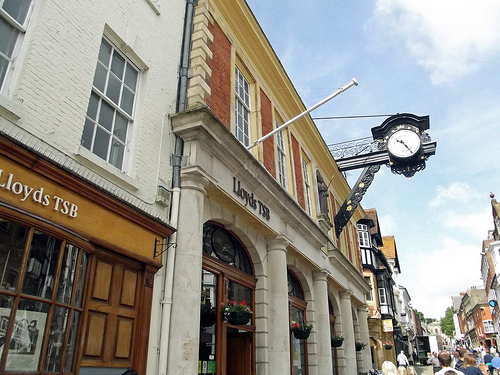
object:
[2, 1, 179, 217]
wall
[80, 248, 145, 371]
door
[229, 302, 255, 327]
basket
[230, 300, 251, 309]
flowers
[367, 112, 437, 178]
clock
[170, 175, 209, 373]
pillar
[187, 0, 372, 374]
building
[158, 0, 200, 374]
downspout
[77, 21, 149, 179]
window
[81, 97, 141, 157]
panes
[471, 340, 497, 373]
people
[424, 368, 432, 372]
street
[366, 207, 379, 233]
roof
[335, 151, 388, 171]
beam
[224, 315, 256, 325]
pot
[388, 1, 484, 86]
clouds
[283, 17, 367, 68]
sky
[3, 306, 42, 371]
advertisement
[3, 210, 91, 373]
window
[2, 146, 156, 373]
store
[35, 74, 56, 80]
bricks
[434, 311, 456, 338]
trees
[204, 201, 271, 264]
archway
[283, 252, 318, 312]
archway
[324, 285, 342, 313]
archway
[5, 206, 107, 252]
frame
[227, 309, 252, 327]
plant hanger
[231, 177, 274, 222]
lloyds tsb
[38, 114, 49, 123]
brick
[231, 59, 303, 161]
window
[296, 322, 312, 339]
flower pot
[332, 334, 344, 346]
flower pot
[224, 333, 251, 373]
door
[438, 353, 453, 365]
head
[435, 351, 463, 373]
person